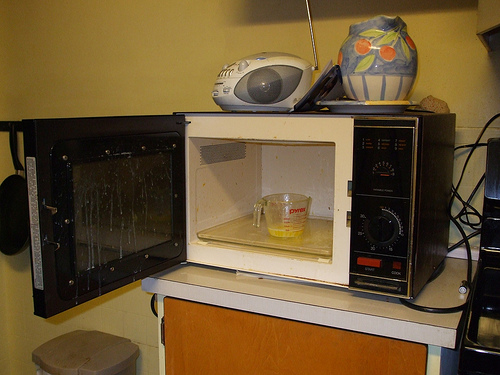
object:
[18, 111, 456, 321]
microwave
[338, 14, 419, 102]
jar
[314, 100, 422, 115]
plate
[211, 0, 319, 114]
radio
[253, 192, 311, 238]
cup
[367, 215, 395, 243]
knob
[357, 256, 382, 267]
button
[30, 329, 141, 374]
stool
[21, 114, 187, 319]
door